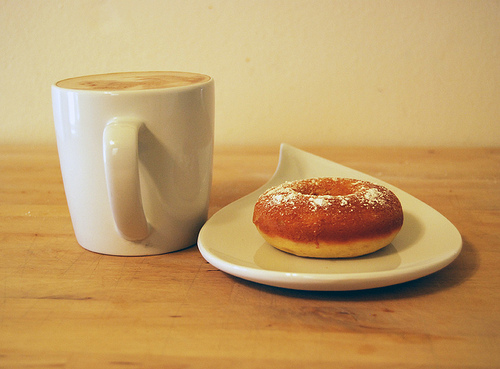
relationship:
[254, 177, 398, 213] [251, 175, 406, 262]
sugar on doughnut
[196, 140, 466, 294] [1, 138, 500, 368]
plate on table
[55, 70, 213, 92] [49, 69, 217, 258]
liquid in mug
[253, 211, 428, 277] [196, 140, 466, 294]
shadow on plate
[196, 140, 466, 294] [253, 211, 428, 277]
plate has shadow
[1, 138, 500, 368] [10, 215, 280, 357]
table has scratches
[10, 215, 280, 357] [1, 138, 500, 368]
scratches on table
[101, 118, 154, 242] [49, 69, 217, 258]
handle on coffee cup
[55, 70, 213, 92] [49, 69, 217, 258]
liquid in coffee cup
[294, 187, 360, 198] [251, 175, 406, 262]
hole in doughnut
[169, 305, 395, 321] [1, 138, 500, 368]
spots on table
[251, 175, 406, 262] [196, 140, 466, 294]
doughnut on dish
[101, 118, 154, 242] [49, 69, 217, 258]
handle on dish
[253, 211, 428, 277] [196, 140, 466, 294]
shadow on dish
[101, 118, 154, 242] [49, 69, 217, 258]
handle on cup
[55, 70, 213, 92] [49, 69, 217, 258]
drink in cup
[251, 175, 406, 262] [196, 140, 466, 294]
doughnut on plate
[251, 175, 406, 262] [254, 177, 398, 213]
doughnut has sugar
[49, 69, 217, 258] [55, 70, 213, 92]
cup has coffee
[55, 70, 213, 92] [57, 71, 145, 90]
coffee has cream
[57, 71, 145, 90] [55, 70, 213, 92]
cream in coffee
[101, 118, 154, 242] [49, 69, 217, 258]
handle on mug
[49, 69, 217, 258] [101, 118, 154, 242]
mug has handle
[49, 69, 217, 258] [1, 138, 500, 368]
item on table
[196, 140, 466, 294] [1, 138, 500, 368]
item on table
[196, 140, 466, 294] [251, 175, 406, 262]
plate under doughnut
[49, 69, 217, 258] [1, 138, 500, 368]
mug on table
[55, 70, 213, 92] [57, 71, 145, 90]
coffee has foam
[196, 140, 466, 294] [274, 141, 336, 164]
plate has point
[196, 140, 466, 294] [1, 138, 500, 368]
saucer on table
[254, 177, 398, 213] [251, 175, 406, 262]
sprinkles on doughnut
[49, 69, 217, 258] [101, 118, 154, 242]
cup has handle